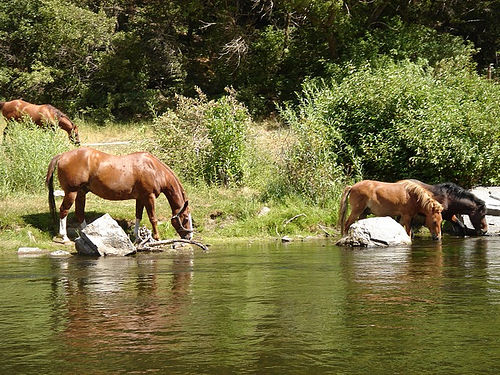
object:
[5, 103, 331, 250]
grass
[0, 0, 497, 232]
forest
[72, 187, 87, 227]
leg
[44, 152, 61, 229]
tail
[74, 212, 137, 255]
rock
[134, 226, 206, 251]
branch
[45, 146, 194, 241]
horse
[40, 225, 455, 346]
pond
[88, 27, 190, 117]
trees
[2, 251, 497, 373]
lake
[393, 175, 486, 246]
horse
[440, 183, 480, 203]
mane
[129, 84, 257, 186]
bush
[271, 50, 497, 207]
bush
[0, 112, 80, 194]
bush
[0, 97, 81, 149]
horse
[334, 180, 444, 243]
horse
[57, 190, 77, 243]
leg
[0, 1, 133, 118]
tree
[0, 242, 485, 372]
water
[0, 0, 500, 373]
wilderness